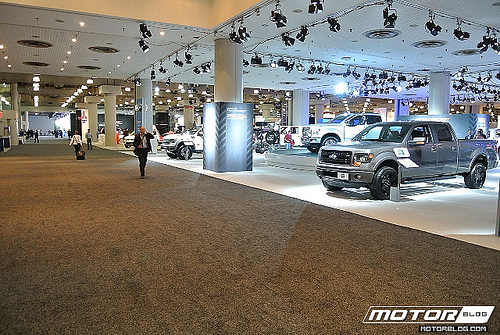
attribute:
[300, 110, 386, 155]
truck — white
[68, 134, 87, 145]
shirt — white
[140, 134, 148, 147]
shirt — white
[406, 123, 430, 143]
window — down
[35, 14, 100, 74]
lights — silver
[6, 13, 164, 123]
ceiling — white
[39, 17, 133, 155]
lights — silver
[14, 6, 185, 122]
ceiling — white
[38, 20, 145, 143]
lights — silver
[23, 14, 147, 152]
ceiling — white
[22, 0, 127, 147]
lights — silver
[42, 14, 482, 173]
ceiling — white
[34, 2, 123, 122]
lights — silver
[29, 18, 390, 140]
ceiling — white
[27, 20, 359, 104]
ceiling — white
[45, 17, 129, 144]
lights — silver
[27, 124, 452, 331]
carpet — Brown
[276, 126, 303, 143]
shirt — Brownred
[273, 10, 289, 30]
light — silver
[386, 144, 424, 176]
label — white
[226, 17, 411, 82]
lights — above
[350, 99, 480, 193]
truck — white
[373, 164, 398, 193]
rim — black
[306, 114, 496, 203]
truck — black, new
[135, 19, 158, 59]
light — silver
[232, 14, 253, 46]
light — silver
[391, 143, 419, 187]
display — information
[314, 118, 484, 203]
truck — large, gray, Ford, parked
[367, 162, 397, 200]
tire — large, round, black, rubber